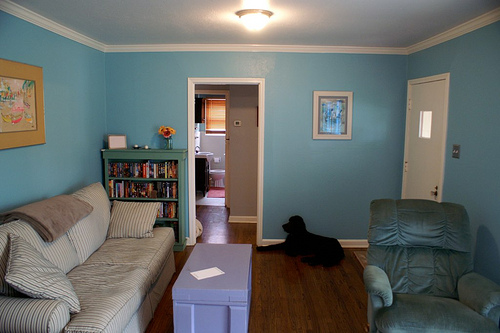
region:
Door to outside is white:
[398, 76, 452, 201]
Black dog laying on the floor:
[260, 215, 345, 268]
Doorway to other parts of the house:
[185, 76, 267, 243]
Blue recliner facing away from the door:
[366, 197, 482, 329]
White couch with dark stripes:
[0, 181, 176, 328]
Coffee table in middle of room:
[175, 242, 254, 332]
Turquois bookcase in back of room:
[100, 146, 192, 242]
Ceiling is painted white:
[2, 1, 498, 57]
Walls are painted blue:
[107, 55, 182, 125]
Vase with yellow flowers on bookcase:
[157, 122, 181, 150]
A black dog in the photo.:
[260, 216, 347, 269]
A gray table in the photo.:
[174, 239, 250, 331]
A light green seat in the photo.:
[364, 192, 489, 331]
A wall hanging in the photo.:
[307, 87, 361, 144]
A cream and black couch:
[0, 185, 172, 330]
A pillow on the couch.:
[7, 234, 82, 310]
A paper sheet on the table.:
[192, 267, 229, 282]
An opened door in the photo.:
[189, 82, 260, 244]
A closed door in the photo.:
[402, 82, 447, 196]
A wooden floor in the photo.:
[257, 265, 335, 325]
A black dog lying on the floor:
[255, 213, 352, 275]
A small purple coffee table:
[165, 234, 259, 331]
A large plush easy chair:
[356, 192, 498, 329]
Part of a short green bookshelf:
[97, 142, 189, 253]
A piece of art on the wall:
[309, 88, 355, 145]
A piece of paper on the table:
[185, 264, 229, 284]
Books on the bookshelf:
[105, 158, 177, 178]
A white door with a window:
[395, 69, 447, 215]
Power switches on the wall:
[447, 140, 463, 159]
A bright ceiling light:
[234, 11, 277, 38]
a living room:
[5, 4, 494, 331]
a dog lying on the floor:
[251, 207, 355, 273]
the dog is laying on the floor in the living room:
[253, 209, 359, 282]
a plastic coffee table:
[164, 222, 258, 330]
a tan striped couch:
[6, 171, 178, 331]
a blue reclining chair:
[357, 192, 498, 329]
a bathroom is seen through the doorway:
[193, 80, 232, 230]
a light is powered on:
[228, 8, 300, 47]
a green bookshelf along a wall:
[101, 139, 187, 241]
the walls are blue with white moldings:
[0, 12, 495, 258]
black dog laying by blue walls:
[265, 208, 346, 277]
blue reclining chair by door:
[357, 197, 485, 332]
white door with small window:
[393, 75, 454, 195]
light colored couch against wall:
[8, 178, 195, 332]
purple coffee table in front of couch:
[164, 230, 266, 332]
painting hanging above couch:
[3, 54, 48, 155]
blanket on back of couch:
[12, 186, 107, 242]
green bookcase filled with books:
[104, 142, 192, 243]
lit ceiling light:
[218, 6, 285, 31]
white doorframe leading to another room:
[177, 75, 272, 240]